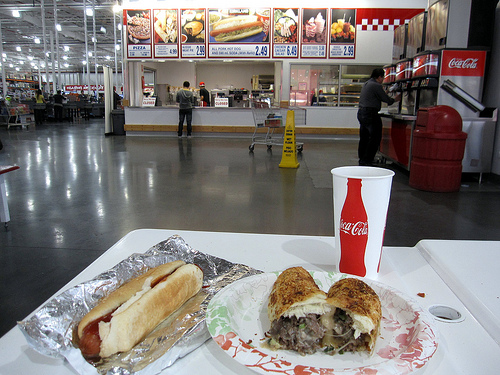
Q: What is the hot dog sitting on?
A: Tin foil.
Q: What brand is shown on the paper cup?
A: Coca Cola.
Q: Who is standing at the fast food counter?
A: A man.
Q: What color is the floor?
A: Gray.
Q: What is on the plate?
A: Sandwich.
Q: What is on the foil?
A: Hotdog.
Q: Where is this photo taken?
A: Food court.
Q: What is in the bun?
A: Hot dog.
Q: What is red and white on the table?
A: Cup.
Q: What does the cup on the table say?
A: Coca cola.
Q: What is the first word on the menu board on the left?
A: Pizza.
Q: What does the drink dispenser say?
A: Coca Cola.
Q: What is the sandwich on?
A: Plate.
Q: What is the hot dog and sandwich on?
A: Table.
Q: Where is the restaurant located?
A: Inside of a store.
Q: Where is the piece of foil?
A: Under the hot dog.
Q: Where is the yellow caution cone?
A: On the floor.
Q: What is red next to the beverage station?
A: A trash bin.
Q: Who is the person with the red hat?
A: An employee.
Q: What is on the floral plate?
A: A sandwich.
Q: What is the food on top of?
A: A white table.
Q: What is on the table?
A: Food.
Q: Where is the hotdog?
A: Foil.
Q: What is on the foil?
A: Hot dog.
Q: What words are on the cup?
A: Coca Cola.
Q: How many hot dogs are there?
A: One.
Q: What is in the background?
A: Yellow caution sign.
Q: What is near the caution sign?
A: Shopping cart.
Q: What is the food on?
A: Table.